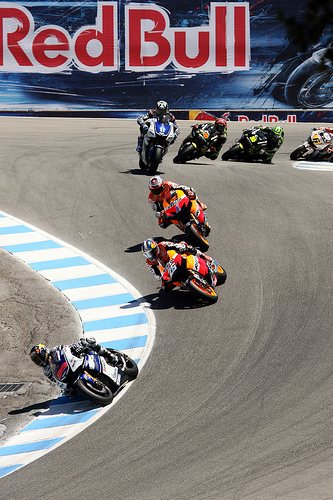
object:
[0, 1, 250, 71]
letter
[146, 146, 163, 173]
wheel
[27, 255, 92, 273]
line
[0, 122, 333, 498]
road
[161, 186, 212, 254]
motorcycle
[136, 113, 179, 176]
motorcycle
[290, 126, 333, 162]
motorcycle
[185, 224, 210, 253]
tire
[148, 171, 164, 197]
helmet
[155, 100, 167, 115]
helmet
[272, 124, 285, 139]
helmet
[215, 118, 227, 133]
helmet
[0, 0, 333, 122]
ad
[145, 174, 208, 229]
biker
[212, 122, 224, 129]
glasses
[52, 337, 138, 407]
motorcycle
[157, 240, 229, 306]
motorcycle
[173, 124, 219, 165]
motorcycle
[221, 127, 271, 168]
motorcycle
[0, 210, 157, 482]
stripes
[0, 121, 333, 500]
track